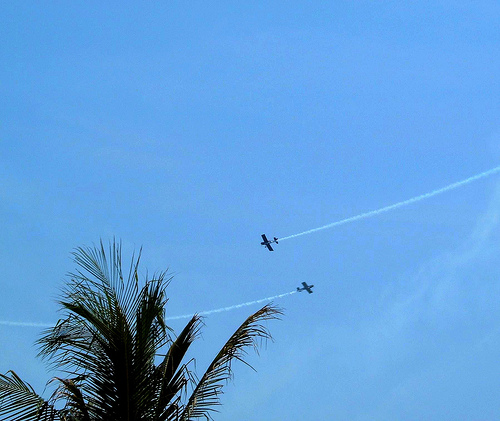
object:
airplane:
[260, 231, 279, 254]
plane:
[297, 280, 315, 295]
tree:
[0, 233, 283, 419]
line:
[279, 164, 498, 243]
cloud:
[378, 202, 497, 331]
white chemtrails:
[0, 288, 295, 330]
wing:
[260, 232, 268, 241]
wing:
[301, 279, 309, 289]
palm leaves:
[176, 301, 283, 419]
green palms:
[1, 233, 283, 420]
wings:
[260, 234, 272, 251]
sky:
[2, 0, 500, 420]